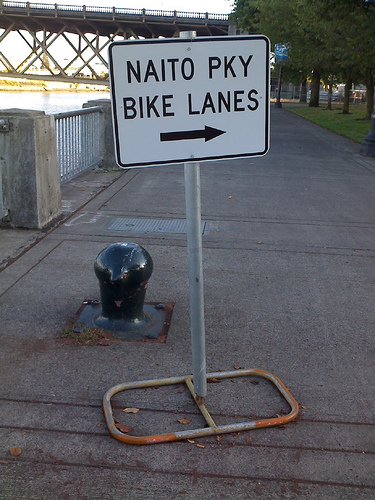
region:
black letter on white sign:
[125, 59, 142, 82]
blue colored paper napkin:
[166, 57, 179, 81]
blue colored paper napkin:
[181, 56, 197, 80]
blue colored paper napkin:
[237, 53, 253, 77]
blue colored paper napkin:
[122, 97, 137, 118]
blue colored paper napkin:
[138, 96, 144, 118]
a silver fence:
[50, 108, 105, 180]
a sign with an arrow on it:
[108, 45, 275, 157]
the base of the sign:
[99, 366, 305, 442]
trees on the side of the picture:
[236, 4, 373, 117]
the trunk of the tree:
[310, 74, 319, 107]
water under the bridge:
[4, 88, 81, 109]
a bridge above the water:
[2, 2, 117, 83]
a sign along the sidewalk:
[276, 45, 294, 106]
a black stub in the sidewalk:
[88, 242, 160, 340]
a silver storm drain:
[107, 217, 189, 235]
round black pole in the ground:
[62, 231, 179, 354]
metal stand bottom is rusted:
[106, 427, 178, 448]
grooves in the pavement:
[13, 398, 74, 476]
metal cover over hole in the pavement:
[111, 216, 201, 241]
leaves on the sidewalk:
[121, 400, 193, 430]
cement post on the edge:
[2, 110, 77, 229]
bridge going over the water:
[19, 0, 136, 52]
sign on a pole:
[102, 28, 286, 168]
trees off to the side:
[259, 13, 366, 117]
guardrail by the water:
[46, 105, 115, 173]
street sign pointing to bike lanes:
[108, 22, 286, 178]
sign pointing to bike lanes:
[92, 19, 290, 211]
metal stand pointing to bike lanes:
[103, 18, 279, 254]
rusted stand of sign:
[101, 364, 309, 464]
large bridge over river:
[15, 0, 87, 102]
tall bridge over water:
[17, 0, 96, 96]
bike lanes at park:
[106, 26, 280, 336]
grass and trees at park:
[283, 3, 363, 136]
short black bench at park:
[80, 231, 173, 354]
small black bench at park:
[86, 226, 158, 337]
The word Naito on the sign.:
[124, 57, 196, 82]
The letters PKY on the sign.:
[204, 52, 253, 79]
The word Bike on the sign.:
[121, 94, 175, 118]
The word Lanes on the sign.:
[186, 90, 258, 116]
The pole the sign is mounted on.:
[185, 164, 211, 398]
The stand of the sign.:
[100, 364, 298, 441]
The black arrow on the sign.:
[155, 125, 227, 140]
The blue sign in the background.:
[272, 44, 290, 60]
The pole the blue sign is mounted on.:
[279, 67, 284, 102]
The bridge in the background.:
[5, 1, 265, 36]